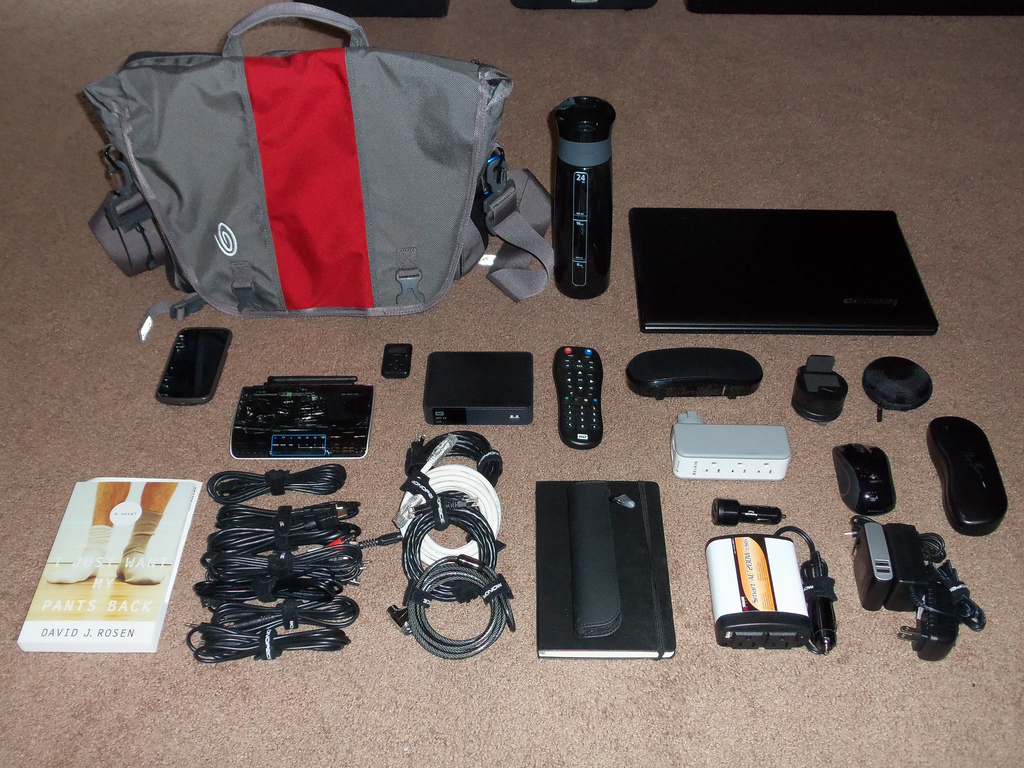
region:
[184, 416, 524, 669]
Cords on the ground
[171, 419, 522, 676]
Cords are on the ground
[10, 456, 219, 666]
Book on the ground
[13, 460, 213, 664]
Book is on the ground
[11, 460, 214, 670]
Book on the carpet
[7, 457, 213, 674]
Book is on the carpet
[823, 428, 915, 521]
Mouse on the ground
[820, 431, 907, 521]
Mouse is on the ground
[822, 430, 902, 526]
Mouse on the carpet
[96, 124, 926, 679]
this is a bunch of gear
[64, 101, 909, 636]
these are electronics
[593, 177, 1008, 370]
the laptop is black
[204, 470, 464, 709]
the cords are bunched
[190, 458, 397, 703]
the cords are tied up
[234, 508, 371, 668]
the cords are black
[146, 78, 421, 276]
the bag is gray and red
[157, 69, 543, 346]
this is a shoulder bag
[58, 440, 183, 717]
this is a book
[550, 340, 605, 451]
a black remote control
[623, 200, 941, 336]
a closed laptop computer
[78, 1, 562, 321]
a grey and red bag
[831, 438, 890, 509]
a black computer mouse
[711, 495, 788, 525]
a car charger plug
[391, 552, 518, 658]
a wound up wire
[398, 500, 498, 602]
a wound up wire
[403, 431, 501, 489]
a wound up wire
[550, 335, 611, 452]
Black colored remote control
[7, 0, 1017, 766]
Tan colored carpet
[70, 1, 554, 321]
Gray and red nylon bag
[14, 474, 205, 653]
Book with a picture of a person in socks on the cover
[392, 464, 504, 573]
White ethernet cable wrapped in a circle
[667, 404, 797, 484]
White and gray colored power strip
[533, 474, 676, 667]
Black notebook with a strap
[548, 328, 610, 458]
remote control on the rug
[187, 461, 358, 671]
bunch of cables on the rug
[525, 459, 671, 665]
book in a case on the floor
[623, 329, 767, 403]
eyeglasses case on the rug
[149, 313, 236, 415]
cellphone on the rug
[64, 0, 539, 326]
gray bag with red middle on the floor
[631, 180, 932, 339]
black laptop on the floor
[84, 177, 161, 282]
strap on the bag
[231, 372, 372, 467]
radio on the rug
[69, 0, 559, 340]
A grey bag with red stripe.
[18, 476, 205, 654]
White book with socks on feet on the top.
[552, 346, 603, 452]
Black remote with red and blue buttons on the top.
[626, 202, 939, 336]
A black rectangle laptop.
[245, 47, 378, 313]
A thick red stripe on a grey bag.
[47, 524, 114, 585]
A white sock on a foot.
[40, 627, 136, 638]
The name DAVID J. ROSEN.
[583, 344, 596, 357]
A round blue button on a remote.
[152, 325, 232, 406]
A black cell phone.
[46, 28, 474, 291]
gray and red bag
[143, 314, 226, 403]
black electronics on brown table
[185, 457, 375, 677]
black electronics on brown table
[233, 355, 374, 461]
black electronics on brown table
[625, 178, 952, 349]
black electronics on brown table